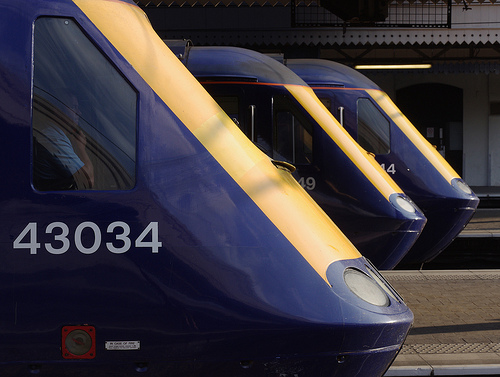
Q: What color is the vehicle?
A: Blue.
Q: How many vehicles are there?
A: Three.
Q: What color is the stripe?
A: Yellow.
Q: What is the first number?
A: 43034.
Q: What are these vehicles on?
A: Tracks.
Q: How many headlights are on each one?
A: Two.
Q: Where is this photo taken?
A: Train station.